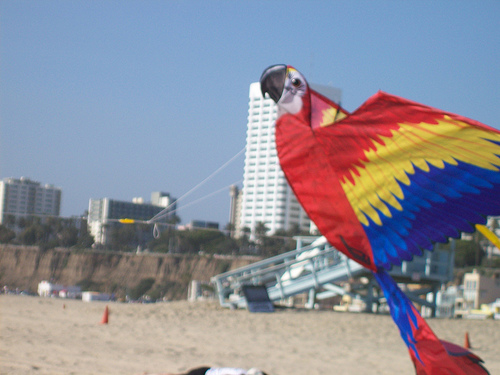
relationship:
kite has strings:
[260, 63, 500, 374] [147, 119, 279, 239]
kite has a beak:
[260, 63, 500, 374] [256, 64, 289, 98]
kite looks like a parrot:
[260, 63, 500, 374] [260, 64, 496, 374]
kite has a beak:
[260, 63, 500, 374] [260, 64, 289, 104]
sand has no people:
[1, 293, 498, 374] [7, 289, 499, 373]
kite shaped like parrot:
[260, 63, 500, 374] [259, 64, 497, 374]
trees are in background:
[21, 221, 96, 254] [7, 177, 499, 291]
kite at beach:
[260, 63, 500, 374] [0, 292, 499, 374]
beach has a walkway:
[0, 292, 499, 374] [215, 237, 389, 309]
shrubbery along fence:
[7, 224, 293, 256] [7, 247, 271, 263]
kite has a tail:
[260, 63, 500, 374] [373, 272, 492, 374]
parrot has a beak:
[260, 64, 496, 374] [260, 64, 289, 104]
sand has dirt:
[1, 293, 498, 374] [4, 294, 496, 373]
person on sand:
[186, 368, 268, 374] [1, 293, 498, 374]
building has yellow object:
[107, 221, 179, 254] [121, 219, 134, 223]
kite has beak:
[260, 63, 500, 374] [260, 64, 289, 104]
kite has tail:
[260, 63, 500, 374] [373, 272, 492, 374]